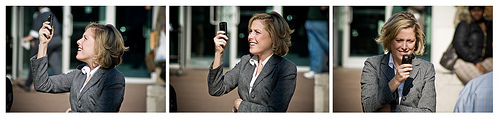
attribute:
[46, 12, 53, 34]
phone — cell, black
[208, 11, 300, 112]
woman — confused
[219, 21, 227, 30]
phone — black, mobile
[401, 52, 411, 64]
phone — black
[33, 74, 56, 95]
elbow — bent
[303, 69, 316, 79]
shoe — white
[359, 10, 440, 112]
woman — smiling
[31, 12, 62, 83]
clothes — dark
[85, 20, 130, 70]
hair — blonde, short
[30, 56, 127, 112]
suit — grey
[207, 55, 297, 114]
suit — grey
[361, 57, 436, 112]
suit — gray, grey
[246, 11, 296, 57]
hair — blonde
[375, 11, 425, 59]
hair — blonde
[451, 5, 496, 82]
person — sitting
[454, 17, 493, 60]
jacket — black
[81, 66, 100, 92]
shirt — white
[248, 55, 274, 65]
collar — open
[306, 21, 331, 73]
jeans — blue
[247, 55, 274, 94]
shirt — white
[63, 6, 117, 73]
door — glass